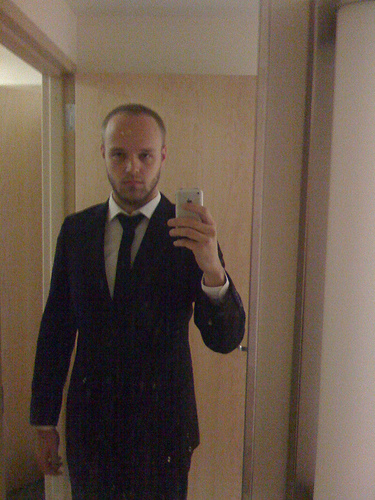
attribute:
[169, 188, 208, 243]
cellphone — white, mobile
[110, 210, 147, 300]
tie — black, professional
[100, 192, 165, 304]
shirt — white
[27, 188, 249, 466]
coat — black, dress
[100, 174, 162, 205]
beard — mans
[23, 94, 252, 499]
man — taking selfie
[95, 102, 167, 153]
hair — short, short cropped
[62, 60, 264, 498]
door — brown, light wood, open, brown wooden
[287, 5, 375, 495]
wall — white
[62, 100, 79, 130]
hinge — silver, white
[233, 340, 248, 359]
handle — silver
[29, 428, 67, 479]
hand — empty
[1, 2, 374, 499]
mirror — dirty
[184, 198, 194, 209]
logo — black, apple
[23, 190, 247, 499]
suit — black, dressy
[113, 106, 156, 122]
hairline — receding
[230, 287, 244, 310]
cuffs — buttoned